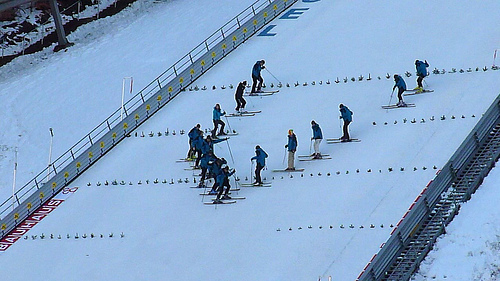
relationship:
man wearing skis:
[226, 83, 250, 109] [229, 110, 255, 117]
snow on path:
[129, 30, 146, 39] [321, 32, 361, 55]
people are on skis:
[193, 131, 282, 189] [229, 110, 255, 117]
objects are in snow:
[116, 169, 172, 190] [129, 30, 146, 39]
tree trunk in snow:
[54, 34, 71, 46] [129, 30, 146, 39]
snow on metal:
[129, 30, 146, 39] [263, 18, 278, 26]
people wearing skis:
[248, 144, 270, 188] [229, 110, 255, 117]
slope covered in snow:
[177, 224, 228, 256] [129, 30, 146, 39]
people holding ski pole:
[248, 144, 270, 188] [237, 165, 257, 177]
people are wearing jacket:
[193, 131, 282, 189] [186, 131, 198, 148]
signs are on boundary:
[227, 22, 253, 37] [159, 46, 220, 78]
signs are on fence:
[227, 22, 253, 37] [157, 68, 187, 89]